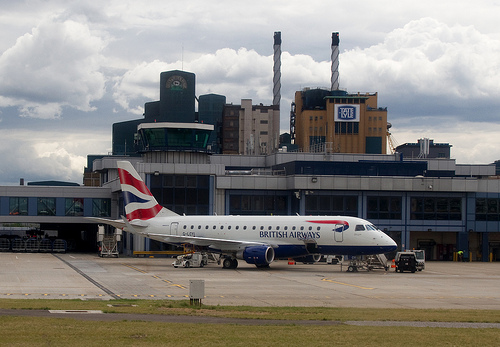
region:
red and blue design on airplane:
[104, 158, 179, 233]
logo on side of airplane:
[255, 227, 333, 244]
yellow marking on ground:
[118, 258, 187, 300]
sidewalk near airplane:
[67, 303, 496, 333]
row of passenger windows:
[182, 223, 324, 233]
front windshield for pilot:
[352, 219, 384, 233]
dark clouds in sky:
[22, 16, 92, 140]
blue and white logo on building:
[326, 93, 368, 121]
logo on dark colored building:
[162, 69, 204, 96]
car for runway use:
[392, 248, 437, 285]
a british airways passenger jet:
[90, 159, 402, 268]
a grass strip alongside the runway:
[0, 298, 497, 343]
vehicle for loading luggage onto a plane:
[176, 251, 213, 268]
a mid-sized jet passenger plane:
[96, 162, 398, 272]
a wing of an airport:
[3, 167, 495, 253]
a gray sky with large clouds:
[10, 0, 496, 176]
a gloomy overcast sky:
[2, 1, 495, 179]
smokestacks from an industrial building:
[273, 32, 338, 109]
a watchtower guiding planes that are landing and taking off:
[134, 122, 216, 154]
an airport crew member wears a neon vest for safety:
[455, 249, 465, 261]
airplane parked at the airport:
[82, 150, 412, 280]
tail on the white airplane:
[83, 150, 161, 242]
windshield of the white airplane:
[351, 220, 384, 235]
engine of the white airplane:
[226, 240, 277, 269]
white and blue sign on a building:
[330, 101, 362, 126]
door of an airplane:
[330, 222, 345, 246]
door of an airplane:
[165, 219, 180, 239]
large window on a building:
[61, 196, 84, 217]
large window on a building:
[9, 193, 31, 218]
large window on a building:
[365, 193, 406, 225]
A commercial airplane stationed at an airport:
[81, 156, 407, 272]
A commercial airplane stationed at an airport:
[78, 156, 428, 278]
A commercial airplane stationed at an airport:
[80, 155, 415, 276]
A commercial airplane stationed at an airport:
[75, 157, 407, 276]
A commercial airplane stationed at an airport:
[76, 150, 417, 275]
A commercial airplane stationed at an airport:
[73, 155, 415, 278]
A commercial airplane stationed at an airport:
[82, 152, 407, 279]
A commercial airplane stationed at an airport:
[79, 154, 411, 278]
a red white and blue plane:
[92, 158, 402, 272]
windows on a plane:
[182, 223, 323, 232]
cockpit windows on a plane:
[355, 222, 376, 232]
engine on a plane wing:
[235, 246, 274, 263]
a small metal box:
[186, 278, 203, 310]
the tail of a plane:
[118, 158, 165, 220]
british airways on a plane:
[257, 228, 322, 238]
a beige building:
[290, 84, 390, 156]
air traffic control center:
[136, 115, 212, 152]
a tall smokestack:
[273, 31, 281, 109]